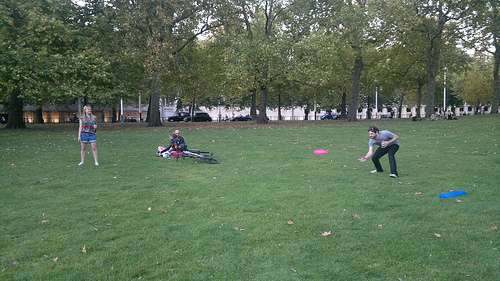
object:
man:
[347, 124, 449, 218]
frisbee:
[295, 133, 340, 175]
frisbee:
[290, 126, 338, 169]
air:
[305, 127, 344, 192]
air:
[274, 126, 385, 226]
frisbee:
[280, 129, 331, 164]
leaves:
[287, 207, 341, 243]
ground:
[272, 211, 377, 260]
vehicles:
[160, 109, 244, 145]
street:
[120, 95, 258, 126]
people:
[48, 92, 485, 221]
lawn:
[143, 164, 413, 239]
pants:
[365, 144, 433, 197]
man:
[353, 104, 427, 193]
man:
[350, 107, 407, 201]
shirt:
[357, 126, 410, 158]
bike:
[184, 144, 240, 178]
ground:
[181, 203, 309, 243]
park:
[178, 179, 318, 235]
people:
[62, 96, 412, 186]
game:
[58, 94, 483, 217]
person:
[341, 122, 411, 188]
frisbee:
[304, 144, 337, 163]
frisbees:
[304, 142, 475, 222]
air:
[18, 36, 475, 241]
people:
[54, 103, 410, 187]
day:
[8, 3, 492, 280]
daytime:
[4, 5, 494, 278]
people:
[50, 97, 422, 201]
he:
[350, 115, 431, 200]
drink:
[375, 136, 395, 152]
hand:
[348, 153, 378, 176]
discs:
[305, 141, 486, 211]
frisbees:
[297, 139, 472, 229]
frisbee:
[314, 136, 350, 171]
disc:
[433, 185, 484, 204]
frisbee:
[276, 141, 375, 168]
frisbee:
[307, 140, 330, 180]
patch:
[195, 199, 316, 239]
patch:
[82, 191, 224, 251]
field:
[4, 111, 498, 279]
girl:
[62, 98, 113, 171]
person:
[295, 118, 417, 204]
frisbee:
[302, 139, 377, 172]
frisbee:
[304, 138, 330, 175]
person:
[357, 117, 410, 183]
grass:
[5, 115, 498, 279]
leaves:
[289, 192, 374, 263]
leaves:
[222, 204, 420, 260]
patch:
[210, 209, 344, 254]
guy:
[339, 115, 426, 187]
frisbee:
[304, 143, 329, 163]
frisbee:
[308, 143, 344, 169]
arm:
[378, 127, 408, 153]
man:
[354, 119, 419, 177]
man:
[348, 120, 408, 185]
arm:
[354, 138, 384, 164]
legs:
[384, 150, 403, 182]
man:
[352, 120, 405, 183]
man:
[356, 123, 406, 188]